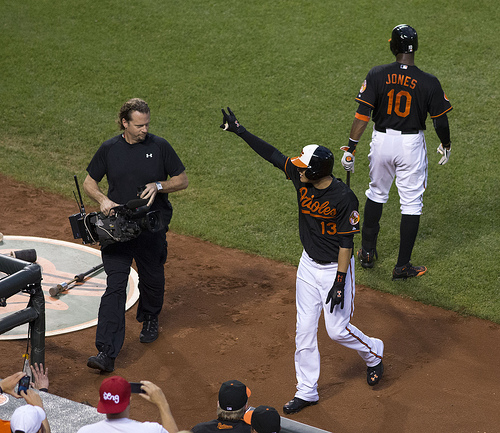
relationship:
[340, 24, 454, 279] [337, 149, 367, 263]
man holding bat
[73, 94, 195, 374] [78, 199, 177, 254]
cameraman holding camera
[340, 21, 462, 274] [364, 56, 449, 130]
man wearing shirt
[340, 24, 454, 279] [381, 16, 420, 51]
man wearing cap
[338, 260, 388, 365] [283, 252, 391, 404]
stripes on pants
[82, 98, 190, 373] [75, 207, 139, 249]
cameraman carrying camera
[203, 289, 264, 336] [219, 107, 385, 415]
dirt near man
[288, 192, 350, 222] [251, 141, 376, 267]
logo on jersey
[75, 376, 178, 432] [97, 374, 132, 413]
man wearing a cap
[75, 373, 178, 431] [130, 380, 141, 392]
man holding camera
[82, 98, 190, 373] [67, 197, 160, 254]
cameraman with camera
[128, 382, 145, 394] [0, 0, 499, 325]
phone pointed at baseball field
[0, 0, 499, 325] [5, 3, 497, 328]
baseball field of baseball field